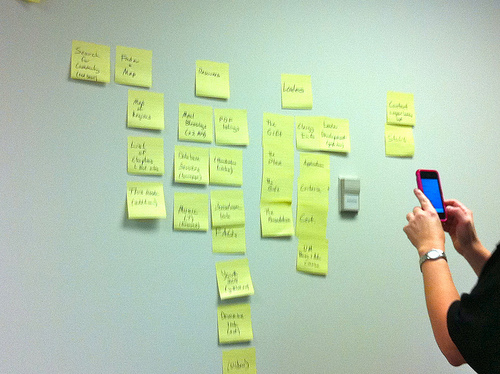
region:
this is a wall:
[25, 120, 106, 327]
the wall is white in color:
[20, 144, 89, 328]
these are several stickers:
[76, 50, 344, 369]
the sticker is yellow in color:
[268, 137, 290, 147]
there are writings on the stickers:
[131, 97, 238, 224]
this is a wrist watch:
[418, 245, 453, 267]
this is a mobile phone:
[415, 167, 448, 221]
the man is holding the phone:
[406, 194, 496, 254]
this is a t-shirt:
[468, 298, 496, 351]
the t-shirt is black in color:
[465, 300, 499, 346]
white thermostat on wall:
[339, 172, 361, 219]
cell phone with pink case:
[416, 166, 449, 223]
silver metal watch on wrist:
[418, 249, 448, 266]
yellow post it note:
[68, 38, 111, 87]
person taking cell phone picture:
[401, 168, 499, 372]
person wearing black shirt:
[398, 167, 498, 372]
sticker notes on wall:
[386, 85, 418, 166]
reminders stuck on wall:
[261, 111, 293, 238]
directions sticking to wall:
[175, 101, 208, 233]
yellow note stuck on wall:
[217, 305, 255, 342]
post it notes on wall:
[107, 46, 250, 235]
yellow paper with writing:
[119, 175, 176, 223]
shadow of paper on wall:
[114, 213, 165, 238]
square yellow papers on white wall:
[168, 95, 259, 197]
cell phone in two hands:
[405, 162, 453, 228]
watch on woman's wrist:
[409, 239, 449, 276]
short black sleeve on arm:
[438, 262, 497, 364]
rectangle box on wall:
[333, 168, 365, 225]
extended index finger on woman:
[406, 183, 431, 219]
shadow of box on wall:
[331, 206, 367, 228]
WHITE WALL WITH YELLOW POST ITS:
[76, 44, 452, 356]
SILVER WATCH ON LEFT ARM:
[415, 240, 437, 270]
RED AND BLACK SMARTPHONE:
[412, 155, 452, 229]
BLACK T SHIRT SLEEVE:
[433, 245, 493, 367]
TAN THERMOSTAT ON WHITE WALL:
[341, 180, 360, 217]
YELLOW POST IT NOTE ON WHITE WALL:
[193, 60, 228, 95]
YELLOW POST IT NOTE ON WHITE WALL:
[210, 260, 267, 300]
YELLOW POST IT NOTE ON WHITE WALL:
[122, 184, 164, 222]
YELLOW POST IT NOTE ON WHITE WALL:
[131, 85, 167, 125]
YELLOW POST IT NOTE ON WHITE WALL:
[76, 30, 111, 81]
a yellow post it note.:
[383, 82, 430, 125]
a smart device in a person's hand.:
[396, 163, 450, 214]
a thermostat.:
[331, 172, 368, 225]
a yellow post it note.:
[116, 177, 170, 238]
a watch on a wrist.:
[413, 238, 452, 273]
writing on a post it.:
[190, 51, 247, 103]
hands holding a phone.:
[405, 160, 483, 235]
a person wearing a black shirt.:
[445, 224, 497, 371]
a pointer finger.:
[400, 174, 434, 216]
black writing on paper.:
[293, 238, 341, 276]